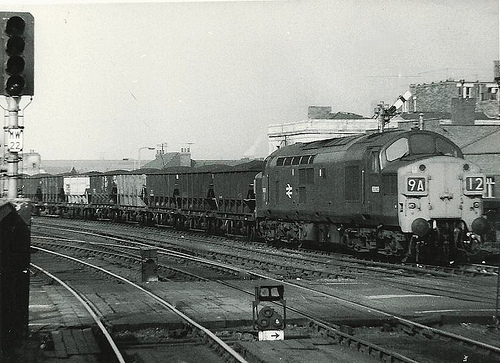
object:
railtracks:
[31, 238, 241, 363]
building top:
[266, 117, 378, 136]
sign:
[258, 330, 284, 342]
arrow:
[271, 332, 280, 338]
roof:
[140, 152, 196, 170]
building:
[129, 142, 195, 172]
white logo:
[285, 183, 292, 199]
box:
[140, 247, 159, 281]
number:
[469, 177, 474, 190]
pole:
[4, 96, 24, 199]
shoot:
[381, 90, 413, 137]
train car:
[174, 171, 214, 229]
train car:
[144, 171, 179, 227]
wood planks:
[47, 328, 100, 363]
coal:
[213, 160, 264, 170]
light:
[0, 11, 35, 97]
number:
[474, 178, 484, 191]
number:
[408, 179, 417, 192]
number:
[15, 142, 20, 150]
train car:
[211, 168, 256, 239]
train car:
[115, 171, 147, 222]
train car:
[61, 174, 90, 219]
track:
[28, 214, 499, 362]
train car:
[89, 172, 115, 219]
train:
[14, 128, 488, 264]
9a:
[408, 178, 425, 192]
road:
[32, 276, 500, 326]